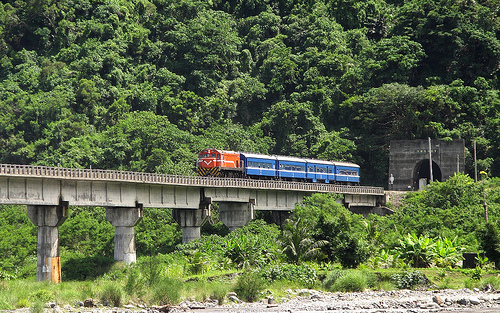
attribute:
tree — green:
[283, 188, 356, 238]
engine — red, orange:
[196, 148, 244, 178]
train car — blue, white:
[240, 149, 278, 180]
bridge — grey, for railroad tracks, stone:
[0, 159, 388, 288]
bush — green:
[391, 233, 441, 270]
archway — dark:
[410, 157, 443, 193]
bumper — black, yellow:
[194, 165, 221, 178]